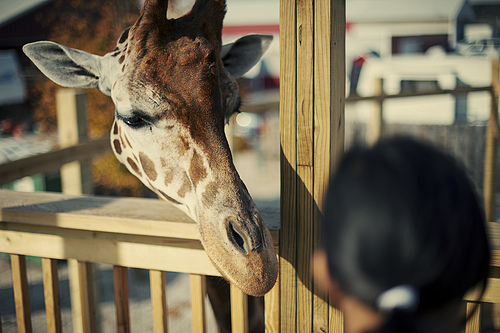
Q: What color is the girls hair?
A: Black.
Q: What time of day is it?
A: Daytime.